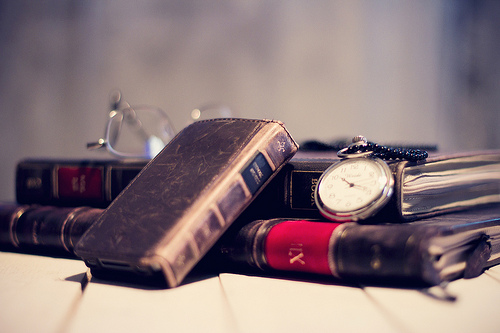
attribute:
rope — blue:
[351, 137, 429, 168]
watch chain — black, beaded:
[336, 135, 423, 183]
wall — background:
[0, 1, 496, 116]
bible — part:
[64, 112, 301, 302]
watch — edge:
[313, 135, 397, 225]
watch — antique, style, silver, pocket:
[287, 120, 396, 227]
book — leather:
[2, 173, 497, 291]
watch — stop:
[312, 136, 422, 225]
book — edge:
[12, 100, 498, 220]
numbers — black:
[315, 160, 382, 212]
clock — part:
[314, 154, 398, 221]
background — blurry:
[51, 2, 463, 193]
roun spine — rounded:
[7, 195, 461, 295]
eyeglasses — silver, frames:
[87, 88, 237, 170]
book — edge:
[319, 225, 444, 295]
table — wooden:
[5, 244, 494, 329]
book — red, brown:
[257, 200, 431, 281]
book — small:
[78, 115, 297, 286]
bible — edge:
[84, 91, 293, 296]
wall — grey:
[214, 29, 360, 84]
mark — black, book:
[452, 231, 481, 286]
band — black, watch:
[396, 141, 437, 169]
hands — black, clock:
[345, 180, 361, 201]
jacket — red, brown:
[272, 224, 337, 264]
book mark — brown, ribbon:
[458, 231, 493, 282]